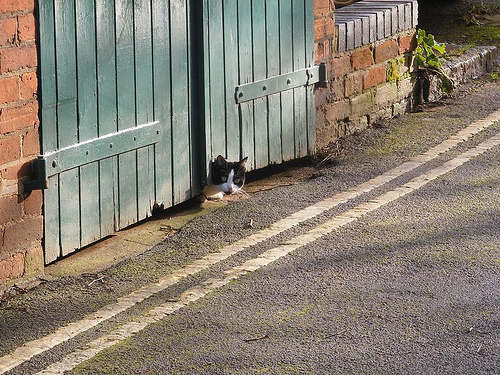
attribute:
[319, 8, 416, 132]
wall — brick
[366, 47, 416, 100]
moss — green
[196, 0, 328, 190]
door — green, slatted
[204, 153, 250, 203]
cat — black, white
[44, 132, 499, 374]
line — white, parallel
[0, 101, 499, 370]
line — white, parallel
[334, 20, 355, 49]
bricks — grey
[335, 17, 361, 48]
bricks — grey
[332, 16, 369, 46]
bricks — grey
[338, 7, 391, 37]
bricks — grey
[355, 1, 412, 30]
bricks — grey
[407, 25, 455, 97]
plant — green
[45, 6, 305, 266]
doors — green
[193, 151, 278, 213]
cat — black, white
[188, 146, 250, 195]
cat — black, white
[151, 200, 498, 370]
ground — concrete, grey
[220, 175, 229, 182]
eye — yellow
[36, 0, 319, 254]
wooden doors — green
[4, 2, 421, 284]
building — brick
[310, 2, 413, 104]
bricks — grey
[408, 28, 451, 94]
plant — green, small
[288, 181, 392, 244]
lines — white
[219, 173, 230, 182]
eye — open, wide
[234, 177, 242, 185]
eye — open, wide